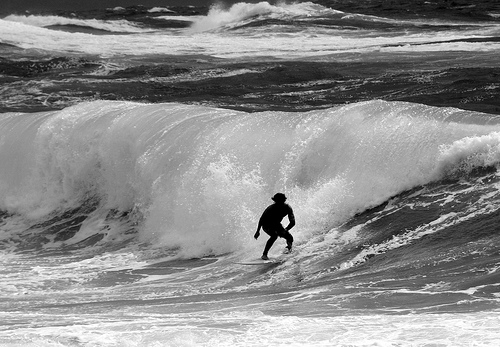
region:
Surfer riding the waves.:
[220, 182, 307, 272]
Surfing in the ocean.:
[220, 180, 300, 270]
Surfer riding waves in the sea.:
[220, 185, 310, 266]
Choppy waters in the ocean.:
[0, 0, 499, 345]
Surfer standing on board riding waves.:
[220, 185, 310, 270]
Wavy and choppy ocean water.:
[0, 0, 499, 345]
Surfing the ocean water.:
[220, 185, 315, 270]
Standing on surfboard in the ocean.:
[220, 185, 320, 270]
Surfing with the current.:
[0, 75, 499, 275]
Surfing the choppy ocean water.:
[0, 1, 498, 343]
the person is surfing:
[241, 181, 306, 265]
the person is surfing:
[232, 171, 324, 299]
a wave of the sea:
[35, 80, 210, 285]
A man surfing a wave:
[238, 185, 330, 275]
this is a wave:
[75, 104, 172, 152]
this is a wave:
[6, 108, 78, 136]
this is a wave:
[149, 125, 281, 171]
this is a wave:
[326, 121, 418, 156]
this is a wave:
[451, 113, 492, 175]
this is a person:
[251, 173, 309, 252]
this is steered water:
[97, 267, 148, 319]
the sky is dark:
[298, 42, 354, 81]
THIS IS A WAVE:
[176, 116, 223, 171]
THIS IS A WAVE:
[356, 145, 434, 176]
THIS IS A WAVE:
[140, 99, 200, 139]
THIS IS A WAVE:
[19, 137, 76, 167]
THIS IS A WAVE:
[19, 85, 98, 182]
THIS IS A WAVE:
[174, 133, 268, 185]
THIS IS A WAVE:
[281, 142, 354, 178]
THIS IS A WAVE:
[364, 175, 420, 269]